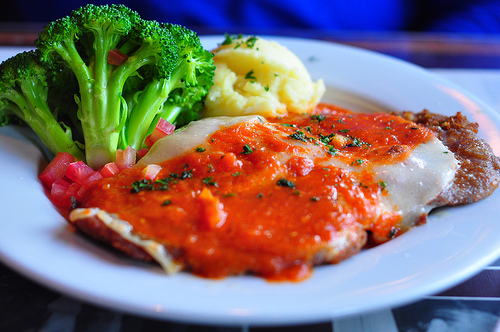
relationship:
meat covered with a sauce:
[59, 104, 496, 281] [70, 105, 422, 255]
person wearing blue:
[186, 7, 485, 22] [182, 11, 472, 21]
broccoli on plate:
[2, 7, 218, 167] [15, 26, 485, 320]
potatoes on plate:
[208, 31, 327, 111] [15, 26, 485, 320]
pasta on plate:
[83, 90, 482, 266] [15, 26, 485, 320]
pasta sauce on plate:
[226, 200, 285, 245] [15, 26, 485, 320]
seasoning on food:
[131, 38, 365, 198] [87, 34, 409, 253]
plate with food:
[15, 26, 485, 320] [8, 20, 470, 263]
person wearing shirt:
[136, 0, 500, 66] [173, 3, 470, 17]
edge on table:
[5, 32, 473, 64] [15, 49, 478, 320]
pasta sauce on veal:
[226, 200, 285, 245] [449, 110, 485, 190]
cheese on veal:
[379, 143, 456, 213] [449, 110, 485, 190]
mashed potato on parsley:
[199, 25, 329, 117] [221, 31, 264, 54]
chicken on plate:
[67, 104, 499, 282] [15, 26, 485, 320]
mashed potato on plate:
[199, 37, 326, 117] [15, 26, 485, 320]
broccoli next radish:
[2, 7, 218, 167] [39, 149, 113, 198]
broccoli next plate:
[2, 7, 218, 167] [15, 26, 485, 320]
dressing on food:
[144, 107, 384, 256] [32, 91, 499, 296]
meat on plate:
[39, 100, 499, 289] [15, 26, 485, 320]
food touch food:
[0, 0, 500, 287] [0, 0, 500, 287]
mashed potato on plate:
[199, 37, 326, 117] [2, 20, 498, 330]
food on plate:
[33, 96, 498, 281] [15, 26, 485, 320]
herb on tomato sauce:
[124, 158, 225, 199] [37, 96, 437, 290]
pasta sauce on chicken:
[226, 200, 285, 245] [67, 104, 499, 282]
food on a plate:
[0, 0, 500, 287] [15, 26, 485, 320]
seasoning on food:
[131, 38, 388, 207] [0, 0, 500, 287]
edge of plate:
[294, 250, 496, 322] [15, 26, 485, 320]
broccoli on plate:
[0, 1, 216, 166] [15, 26, 485, 320]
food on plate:
[0, 0, 500, 287] [15, 26, 485, 320]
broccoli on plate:
[0, 1, 216, 166] [2, 20, 498, 330]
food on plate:
[0, 0, 500, 287] [2, 20, 498, 330]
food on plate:
[33, 96, 498, 281] [2, 20, 498, 330]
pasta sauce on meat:
[226, 200, 285, 245] [66, 112, 463, 274]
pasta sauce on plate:
[80, 100, 439, 283] [2, 20, 498, 330]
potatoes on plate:
[199, 37, 324, 116] [15, 26, 485, 320]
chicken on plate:
[64, 111, 463, 270] [15, 26, 485, 320]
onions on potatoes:
[216, 32, 280, 92] [197, 27, 327, 117]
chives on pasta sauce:
[66, 111, 419, 210] [226, 200, 285, 245]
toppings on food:
[64, 112, 423, 212] [0, 0, 500, 287]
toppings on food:
[215, 30, 283, 90] [0, 0, 500, 287]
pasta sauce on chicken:
[226, 200, 285, 245] [69, 111, 499, 277]